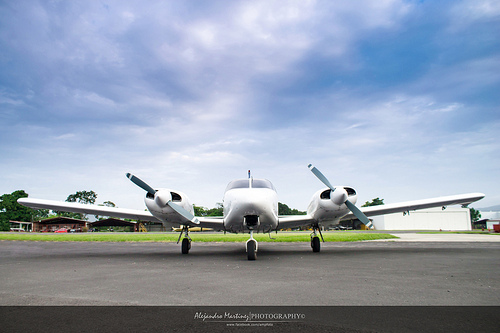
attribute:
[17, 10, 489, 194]
sky — blue, fluffy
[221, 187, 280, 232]
nose — white, painted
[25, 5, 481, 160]
sky — daylit 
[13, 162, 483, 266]
airplane — white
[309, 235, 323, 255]
tire — rubber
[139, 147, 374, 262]
airplane — white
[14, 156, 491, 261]
airplane — white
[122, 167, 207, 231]
propeller — still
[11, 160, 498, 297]
airplane — white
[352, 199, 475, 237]
building — long, white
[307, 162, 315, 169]
stripe — white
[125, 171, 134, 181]
stripe — white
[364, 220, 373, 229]
stripe — white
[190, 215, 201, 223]
stripe — white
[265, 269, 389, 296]
asphalt — black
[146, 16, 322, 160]
cloud — white